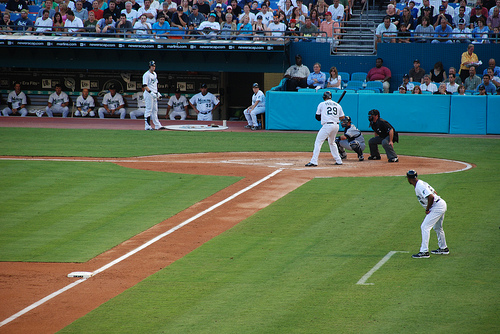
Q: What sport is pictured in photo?
A: Baseball.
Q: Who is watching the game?
A: Spectators.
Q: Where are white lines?
A: On the field.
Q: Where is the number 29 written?
A: On back of batter's uniform.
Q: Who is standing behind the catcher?
A: Umpire.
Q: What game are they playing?
A: Baseball.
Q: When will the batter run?
A: When he hits the ball.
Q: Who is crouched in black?
A: Umpire.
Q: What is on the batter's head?
A: Helmet.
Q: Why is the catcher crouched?
A: To catch the ball.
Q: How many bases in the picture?
A: Two.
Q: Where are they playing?
A: Ball park.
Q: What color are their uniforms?
A: White.